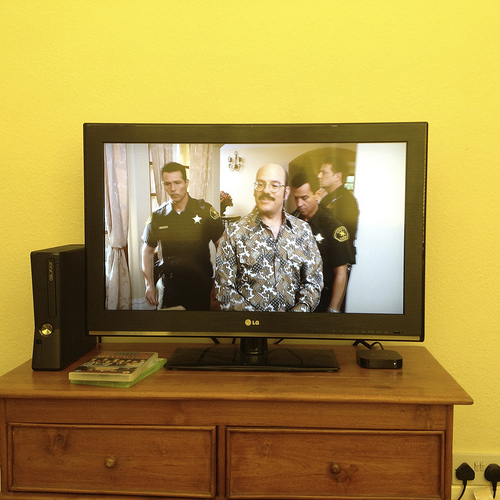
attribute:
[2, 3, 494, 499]
wall — yellow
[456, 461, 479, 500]
plug — black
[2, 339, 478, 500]
dresser — brown, wooden, wood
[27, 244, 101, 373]
xbox — black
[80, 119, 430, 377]
television — black, lg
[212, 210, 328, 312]
shirt — floral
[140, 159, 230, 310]
officer — police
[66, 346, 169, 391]
game — stacked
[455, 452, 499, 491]
outlet — white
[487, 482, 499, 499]
cord — black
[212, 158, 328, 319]
man — arrested